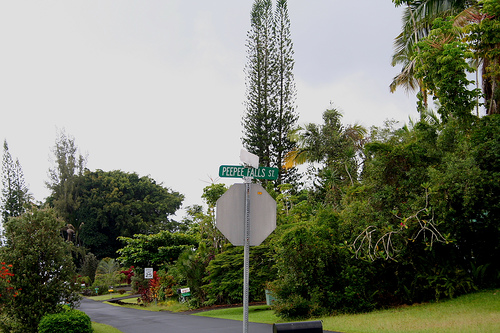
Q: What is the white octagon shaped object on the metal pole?
A: Stop sign.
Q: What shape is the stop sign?
A: Octagon.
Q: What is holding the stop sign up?
A: Metal pole.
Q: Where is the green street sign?
A: Above the stop sign.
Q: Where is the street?
A: To the right of the stop sign.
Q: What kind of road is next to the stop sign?
A: Dark grey and paved.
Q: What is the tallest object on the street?
A: Two tall pine trees in front of the stop sign.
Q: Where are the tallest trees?
A: Lining the paved road.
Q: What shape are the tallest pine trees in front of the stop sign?
A: Thin and long.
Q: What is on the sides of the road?
A: Grass.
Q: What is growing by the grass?
A: Trees.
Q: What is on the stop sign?
A: A street sign.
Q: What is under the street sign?
A: A stop sign.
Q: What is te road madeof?
A: Concrete.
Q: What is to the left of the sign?
A: A small bush.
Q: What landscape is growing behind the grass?
A: Trees.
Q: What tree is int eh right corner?
A: A palm tree.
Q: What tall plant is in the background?
A: A tree.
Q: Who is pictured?
A: No one.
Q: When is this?
A: During the day.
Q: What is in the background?
A: Trees.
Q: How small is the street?
A: Very small.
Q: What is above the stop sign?
A: Street sign.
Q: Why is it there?
A: Directions.